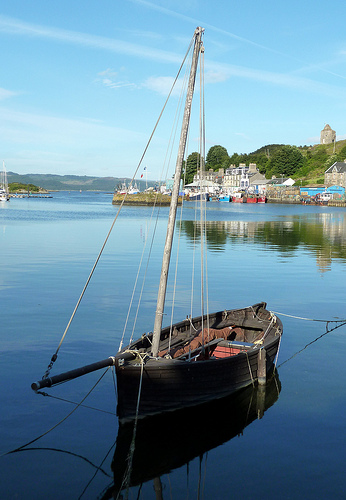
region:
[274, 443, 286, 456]
part of the sea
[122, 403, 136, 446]
part of a lake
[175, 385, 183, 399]
side of a boat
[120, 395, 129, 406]
tip of a boat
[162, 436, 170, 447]
part of a reflection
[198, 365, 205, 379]
edge of a boat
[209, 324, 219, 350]
tip of the ocean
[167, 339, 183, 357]
inside of a boat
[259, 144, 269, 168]
part of a forest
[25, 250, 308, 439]
a sail boat on the water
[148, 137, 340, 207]
A town on the shore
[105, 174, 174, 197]
Boats at a dock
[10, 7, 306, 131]
clouds in th sky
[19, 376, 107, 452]
a anchor rope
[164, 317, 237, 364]
a sail lying a boat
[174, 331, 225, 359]
oars to paddle with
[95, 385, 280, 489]
a shadow of a boat on the water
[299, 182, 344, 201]
a blue building on the shore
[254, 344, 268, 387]
Docking guard protecting boat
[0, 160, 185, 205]
Moutains in the distance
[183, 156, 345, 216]
Properties with a view of the lake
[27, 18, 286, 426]
Sailboat with a missing sail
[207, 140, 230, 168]
Full foliage green tree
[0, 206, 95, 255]
Relatively calm water on the lake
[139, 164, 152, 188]
Red and blue flags raised on a flagpole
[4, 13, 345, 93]
Mist line in the sky from an airplane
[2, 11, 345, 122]
A nearly cloudless blue sky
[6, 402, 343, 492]
Dark murky water on the lake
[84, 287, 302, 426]
A boat on the water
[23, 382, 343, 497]
Reflection of a boat in the water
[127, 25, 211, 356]
A mast on a boat in the water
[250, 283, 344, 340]
A rope tied to a boat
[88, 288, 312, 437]
A wooden boat in the water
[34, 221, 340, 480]
A boat in calm water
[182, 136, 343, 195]
Trees on the hillside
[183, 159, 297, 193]
Buildings near the water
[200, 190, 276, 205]
Boats in the water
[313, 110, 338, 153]
A building in the distance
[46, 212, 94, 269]
The water is flat and blue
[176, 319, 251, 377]
Boat filled with some cargo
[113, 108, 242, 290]
Pole standing straight up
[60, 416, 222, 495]
Reflection in the water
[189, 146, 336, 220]
Buildings on the shore of the water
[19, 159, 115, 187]
Mountains in the background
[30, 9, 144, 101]
The sky is blue with thin clouds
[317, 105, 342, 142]
tower on top of the hill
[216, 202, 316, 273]
The water has a reflection on it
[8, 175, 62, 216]
Island in middle of water